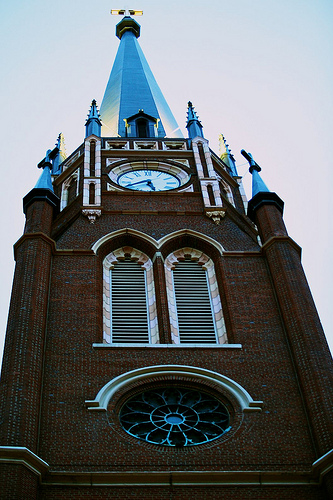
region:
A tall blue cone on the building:
[86, 19, 190, 147]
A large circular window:
[98, 360, 251, 460]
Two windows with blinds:
[83, 232, 259, 362]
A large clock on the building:
[111, 161, 192, 200]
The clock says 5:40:
[104, 158, 187, 198]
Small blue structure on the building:
[28, 122, 66, 200]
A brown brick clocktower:
[9, 164, 328, 496]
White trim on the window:
[78, 365, 276, 419]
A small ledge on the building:
[105, 204, 215, 225]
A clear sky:
[227, 57, 324, 135]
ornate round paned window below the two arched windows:
[88, 365, 264, 447]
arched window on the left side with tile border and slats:
[93, 242, 161, 348]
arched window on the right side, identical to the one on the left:
[164, 244, 229, 350]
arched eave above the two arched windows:
[91, 227, 226, 256]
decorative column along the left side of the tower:
[1, 230, 50, 496]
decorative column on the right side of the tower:
[246, 194, 332, 496]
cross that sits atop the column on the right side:
[238, 148, 271, 192]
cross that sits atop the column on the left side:
[32, 148, 63, 186]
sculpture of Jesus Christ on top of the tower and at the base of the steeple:
[123, 107, 160, 135]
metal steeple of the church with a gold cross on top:
[99, 5, 189, 138]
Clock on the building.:
[17, 122, 228, 224]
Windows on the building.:
[86, 239, 294, 358]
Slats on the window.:
[105, 251, 259, 365]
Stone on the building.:
[46, 406, 186, 484]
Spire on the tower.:
[62, 22, 234, 173]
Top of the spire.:
[91, 2, 163, 39]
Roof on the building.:
[76, 101, 216, 155]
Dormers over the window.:
[81, 217, 253, 258]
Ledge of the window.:
[78, 333, 272, 357]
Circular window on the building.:
[79, 362, 272, 447]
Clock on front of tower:
[98, 140, 223, 211]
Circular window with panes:
[86, 367, 263, 457]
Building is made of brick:
[54, 385, 102, 461]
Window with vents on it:
[82, 229, 241, 358]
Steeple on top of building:
[106, 7, 198, 60]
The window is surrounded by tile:
[158, 249, 239, 367]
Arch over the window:
[80, 362, 267, 400]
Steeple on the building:
[173, 87, 199, 151]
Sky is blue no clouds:
[12, 27, 80, 81]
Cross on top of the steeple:
[108, 9, 148, 30]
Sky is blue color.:
[190, 32, 293, 73]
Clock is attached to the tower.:
[106, 153, 189, 203]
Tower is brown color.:
[33, 266, 91, 374]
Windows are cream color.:
[93, 254, 225, 342]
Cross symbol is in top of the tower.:
[238, 139, 272, 180]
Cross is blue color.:
[233, 138, 272, 182]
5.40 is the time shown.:
[109, 135, 201, 225]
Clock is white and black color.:
[109, 157, 191, 200]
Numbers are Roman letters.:
[112, 162, 190, 213]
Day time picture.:
[17, 23, 296, 279]